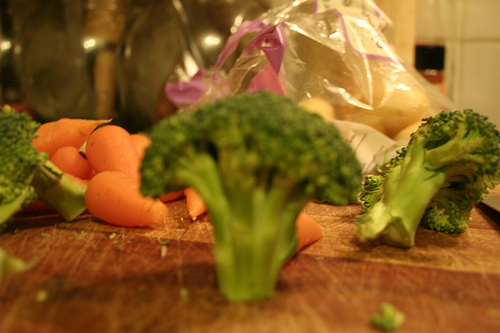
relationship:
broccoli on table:
[138, 88, 368, 304] [0, 197, 498, 331]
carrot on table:
[85, 169, 171, 228] [0, 197, 498, 331]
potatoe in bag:
[335, 64, 430, 131] [162, 1, 460, 131]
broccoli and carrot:
[138, 88, 368, 304] [85, 169, 171, 228]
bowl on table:
[115, 0, 212, 120] [0, 197, 498, 331]